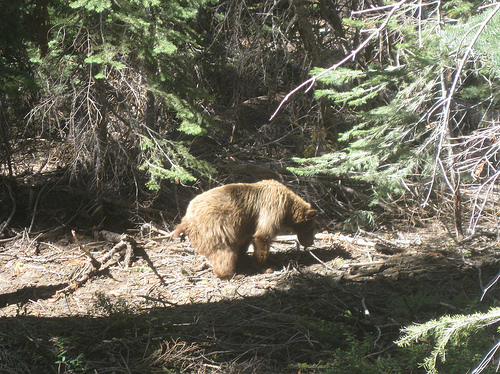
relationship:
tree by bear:
[44, 0, 218, 199] [178, 180, 324, 286]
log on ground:
[68, 215, 161, 280] [8, 116, 491, 372]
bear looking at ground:
[178, 180, 324, 286] [8, 116, 491, 372]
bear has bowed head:
[178, 180, 324, 286] [297, 205, 323, 254]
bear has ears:
[178, 180, 324, 286] [301, 201, 321, 225]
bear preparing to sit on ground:
[178, 180, 324, 286] [8, 116, 491, 372]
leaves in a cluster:
[156, 17, 185, 58] [164, 42, 170, 47]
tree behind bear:
[44, 0, 218, 199] [178, 180, 324, 286]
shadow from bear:
[257, 242, 354, 275] [178, 180, 324, 286]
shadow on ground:
[257, 242, 354, 275] [8, 116, 491, 372]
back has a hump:
[201, 182, 277, 220] [225, 187, 265, 204]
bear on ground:
[178, 180, 324, 286] [8, 116, 491, 372]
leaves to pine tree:
[156, 17, 185, 58] [44, 0, 218, 199]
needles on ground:
[158, 265, 204, 302] [8, 116, 491, 372]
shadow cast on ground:
[257, 242, 354, 275] [8, 116, 491, 372]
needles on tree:
[158, 265, 204, 302] [44, 0, 218, 199]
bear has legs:
[178, 180, 324, 286] [203, 229, 245, 290]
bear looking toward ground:
[178, 180, 324, 286] [8, 116, 491, 372]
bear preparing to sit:
[178, 180, 324, 286] [198, 264, 201, 270]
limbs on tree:
[60, 94, 139, 177] [44, 0, 218, 199]